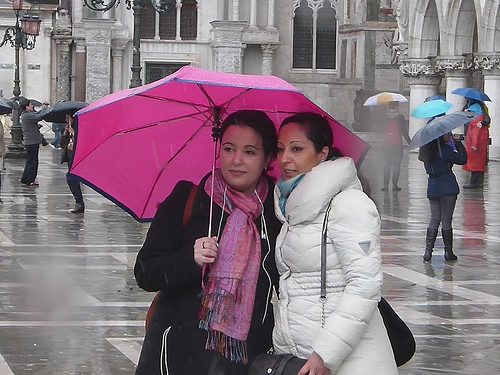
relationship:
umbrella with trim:
[67, 63, 374, 225] [64, 172, 154, 224]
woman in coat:
[272, 111, 398, 374] [273, 160, 400, 375]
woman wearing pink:
[133, 110, 283, 374] [231, 233, 243, 252]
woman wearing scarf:
[133, 110, 283, 374] [201, 171, 269, 363]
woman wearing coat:
[421, 131, 469, 263] [422, 142, 468, 198]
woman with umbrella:
[421, 131, 469, 263] [409, 113, 476, 149]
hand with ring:
[192, 233, 220, 268] [202, 240, 209, 250]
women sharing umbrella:
[132, 110, 396, 375] [67, 63, 374, 225]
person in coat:
[463, 103, 490, 189] [462, 117, 490, 172]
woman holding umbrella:
[272, 111, 398, 374] [67, 63, 374, 225]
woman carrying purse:
[272, 111, 398, 374] [246, 348, 326, 374]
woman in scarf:
[133, 110, 283, 374] [201, 171, 269, 363]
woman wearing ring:
[133, 110, 283, 374] [202, 240, 209, 250]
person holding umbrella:
[382, 102, 412, 193] [363, 92, 409, 106]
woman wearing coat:
[272, 111, 398, 374] [273, 160, 400, 375]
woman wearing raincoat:
[272, 111, 398, 374] [274, 157, 396, 372]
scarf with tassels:
[201, 171, 269, 363] [199, 324, 252, 366]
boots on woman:
[423, 227, 458, 262] [421, 131, 469, 263]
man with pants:
[17, 99, 50, 187] [20, 143, 41, 185]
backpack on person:
[386, 120, 403, 150] [463, 103, 490, 189]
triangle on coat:
[357, 239, 371, 256] [273, 160, 400, 375]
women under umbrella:
[132, 110, 396, 375] [67, 63, 374, 225]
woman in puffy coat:
[272, 111, 398, 374] [273, 160, 400, 375]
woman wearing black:
[133, 110, 283, 374] [147, 249, 174, 276]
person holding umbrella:
[463, 103, 490, 189] [451, 86, 492, 103]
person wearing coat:
[382, 102, 412, 193] [378, 115, 411, 153]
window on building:
[288, 1, 342, 74] [56, 2, 407, 130]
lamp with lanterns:
[1, 1, 42, 159] [19, 14, 43, 36]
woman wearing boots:
[421, 131, 469, 263] [423, 227, 458, 262]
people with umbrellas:
[378, 102, 490, 265] [364, 88, 491, 152]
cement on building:
[89, 29, 112, 83] [56, 2, 407, 130]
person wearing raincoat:
[463, 103, 490, 189] [465, 116, 489, 172]